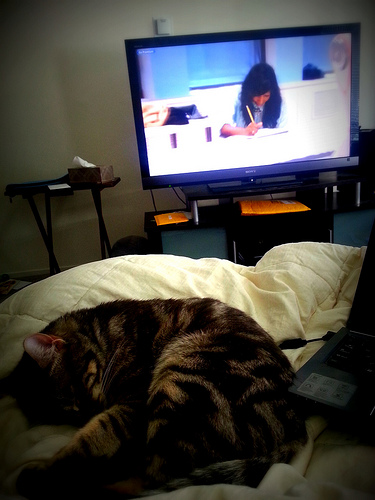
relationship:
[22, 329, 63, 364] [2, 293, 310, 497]
ear of cat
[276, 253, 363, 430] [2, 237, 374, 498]
laptop on bed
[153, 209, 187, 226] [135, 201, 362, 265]
package on table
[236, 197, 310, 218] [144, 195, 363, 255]
package on table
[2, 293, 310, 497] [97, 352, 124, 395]
cat has whisker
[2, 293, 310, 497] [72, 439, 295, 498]
cat has tail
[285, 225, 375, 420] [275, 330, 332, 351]
laptop has cord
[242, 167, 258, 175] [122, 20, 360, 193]
label on television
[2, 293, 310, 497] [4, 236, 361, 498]
cat on blanket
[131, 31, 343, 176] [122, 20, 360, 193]
program on a television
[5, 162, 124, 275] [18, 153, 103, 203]
table loaded with objects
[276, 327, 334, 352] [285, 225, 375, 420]
charge cord for a laptop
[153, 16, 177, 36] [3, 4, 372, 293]
thermostat on a wall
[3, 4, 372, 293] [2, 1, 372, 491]
wall in a room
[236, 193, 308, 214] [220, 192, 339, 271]
manila envelope on a tv stand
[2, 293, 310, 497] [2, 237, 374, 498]
cat on bed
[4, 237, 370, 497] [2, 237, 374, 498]
sheets on bed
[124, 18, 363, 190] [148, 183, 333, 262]
television on stand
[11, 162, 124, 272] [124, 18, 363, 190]
table next to television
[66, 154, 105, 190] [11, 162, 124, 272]
tissue box on table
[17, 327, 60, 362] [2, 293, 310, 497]
ear of cat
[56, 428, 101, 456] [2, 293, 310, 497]
paw of cat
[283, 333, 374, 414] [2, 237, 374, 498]
book on bed